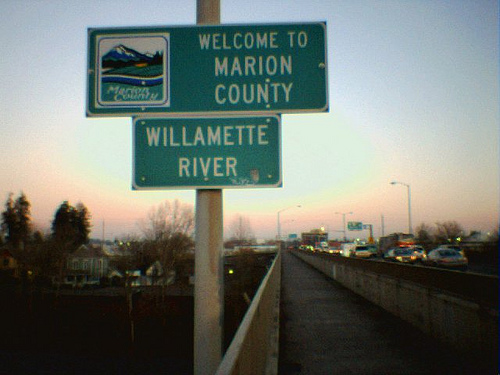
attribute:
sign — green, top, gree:
[89, 24, 333, 116]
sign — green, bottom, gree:
[130, 109, 285, 194]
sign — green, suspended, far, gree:
[346, 218, 369, 232]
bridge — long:
[217, 231, 500, 373]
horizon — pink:
[3, 193, 500, 261]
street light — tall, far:
[388, 177, 416, 240]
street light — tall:
[270, 202, 306, 243]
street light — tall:
[329, 206, 359, 242]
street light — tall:
[372, 202, 391, 238]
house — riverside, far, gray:
[51, 237, 116, 291]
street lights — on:
[261, 177, 429, 255]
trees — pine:
[5, 192, 98, 293]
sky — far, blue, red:
[3, 2, 497, 248]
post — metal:
[190, 4, 228, 373]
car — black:
[421, 249, 477, 278]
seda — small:
[351, 246, 372, 258]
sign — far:
[286, 231, 302, 241]